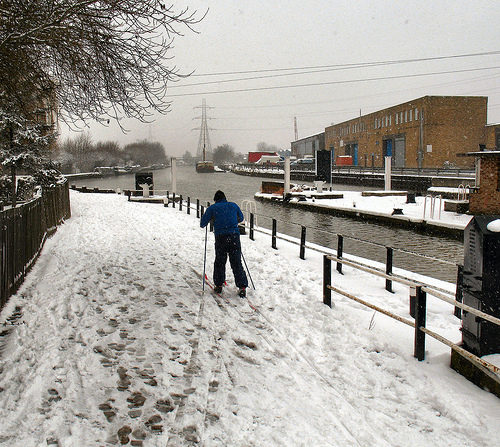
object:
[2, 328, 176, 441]
snow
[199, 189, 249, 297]
skier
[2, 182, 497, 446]
sidewalk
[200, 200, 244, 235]
jacket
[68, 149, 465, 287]
canal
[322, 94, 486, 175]
building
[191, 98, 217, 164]
tower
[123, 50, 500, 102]
power wires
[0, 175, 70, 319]
fence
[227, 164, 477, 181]
railing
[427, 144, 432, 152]
sign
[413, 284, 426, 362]
post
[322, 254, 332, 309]
post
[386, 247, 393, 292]
post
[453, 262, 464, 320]
post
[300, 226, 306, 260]
post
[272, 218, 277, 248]
post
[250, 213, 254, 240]
post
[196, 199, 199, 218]
post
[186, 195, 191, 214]
post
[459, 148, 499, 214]
building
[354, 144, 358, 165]
door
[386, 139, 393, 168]
door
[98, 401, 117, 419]
footprint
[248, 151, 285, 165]
truck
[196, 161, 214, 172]
barge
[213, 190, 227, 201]
cap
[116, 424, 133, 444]
footprint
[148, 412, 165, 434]
footprint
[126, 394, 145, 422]
footprint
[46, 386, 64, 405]
footprint